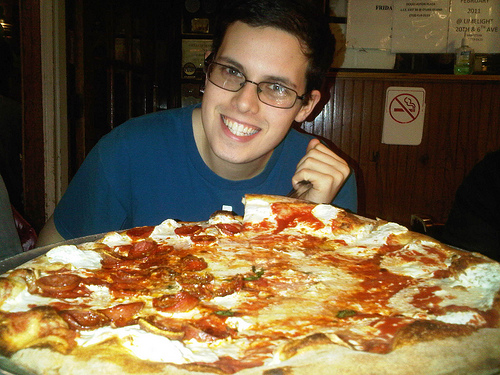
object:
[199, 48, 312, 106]
glasses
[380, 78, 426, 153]
sign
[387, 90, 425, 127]
no smoking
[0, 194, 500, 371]
pizza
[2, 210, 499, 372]
pan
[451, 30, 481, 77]
bottle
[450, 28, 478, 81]
sanitizer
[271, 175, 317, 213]
spatula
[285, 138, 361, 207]
hand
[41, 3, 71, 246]
panel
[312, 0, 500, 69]
wall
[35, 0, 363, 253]
boy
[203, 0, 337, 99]
hair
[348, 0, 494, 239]
back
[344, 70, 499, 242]
wall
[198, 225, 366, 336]
cheese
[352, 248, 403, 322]
sauce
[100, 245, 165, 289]
pepperoni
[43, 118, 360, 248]
shirt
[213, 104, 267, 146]
smile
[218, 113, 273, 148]
teeth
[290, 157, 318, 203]
utensil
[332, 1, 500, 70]
announcements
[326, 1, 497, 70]
board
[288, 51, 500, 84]
shelf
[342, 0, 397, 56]
paper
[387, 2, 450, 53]
sheet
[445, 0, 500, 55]
sheet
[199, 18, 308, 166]
face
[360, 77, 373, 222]
planks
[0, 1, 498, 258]
background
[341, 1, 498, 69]
covers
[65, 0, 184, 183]
door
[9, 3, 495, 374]
scene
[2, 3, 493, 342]
restaurant